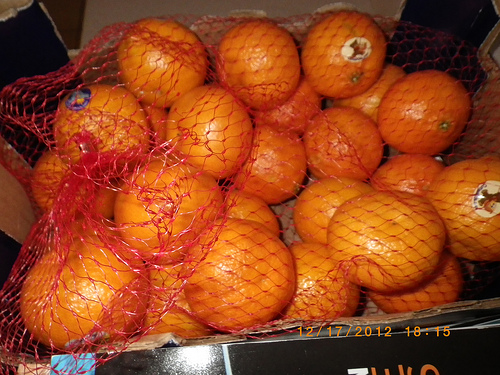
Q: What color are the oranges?
A: The oranges are orange.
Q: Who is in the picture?
A: Nobody is in the picture.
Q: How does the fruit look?
A: The fruit looks good.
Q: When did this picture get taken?
A: It was taken in the night time.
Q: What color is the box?
A: The box is black.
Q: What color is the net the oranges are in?
A: The net is orange.